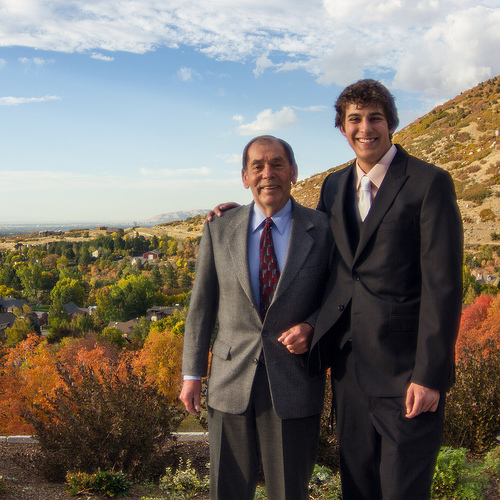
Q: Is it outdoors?
A: Yes, it is outdoors.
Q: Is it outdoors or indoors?
A: It is outdoors.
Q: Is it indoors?
A: No, it is outdoors.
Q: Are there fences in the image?
A: No, there are no fences.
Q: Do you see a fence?
A: No, there are no fences.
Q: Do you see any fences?
A: No, there are no fences.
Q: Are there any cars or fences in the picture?
A: No, there are no fences or cars.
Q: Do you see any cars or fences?
A: No, there are no fences or cars.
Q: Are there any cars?
A: No, there are no cars.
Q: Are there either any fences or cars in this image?
A: No, there are no cars or fences.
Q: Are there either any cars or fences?
A: No, there are no cars or fences.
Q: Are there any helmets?
A: No, there are no helmets.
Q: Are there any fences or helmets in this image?
A: No, there are no helmets or fences.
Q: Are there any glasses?
A: No, there are no glasses.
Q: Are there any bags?
A: No, there are no bags.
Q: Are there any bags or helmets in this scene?
A: No, there are no bags or helmets.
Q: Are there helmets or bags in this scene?
A: No, there are no bags or helmets.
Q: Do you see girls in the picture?
A: No, there are no girls.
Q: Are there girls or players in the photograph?
A: No, there are no girls or players.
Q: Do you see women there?
A: No, there are no women.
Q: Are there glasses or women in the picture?
A: No, there are no women or glasses.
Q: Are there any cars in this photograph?
A: No, there are no cars.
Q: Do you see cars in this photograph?
A: No, there are no cars.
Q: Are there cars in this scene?
A: No, there are no cars.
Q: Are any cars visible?
A: No, there are no cars.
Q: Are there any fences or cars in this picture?
A: No, there are no cars or fences.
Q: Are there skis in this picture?
A: No, there are no skis.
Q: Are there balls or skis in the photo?
A: No, there are no skis or balls.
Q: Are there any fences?
A: No, there are no fences.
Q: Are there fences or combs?
A: No, there are no fences or combs.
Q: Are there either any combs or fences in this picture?
A: No, there are no fences or combs.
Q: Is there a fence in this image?
A: No, there are no fences.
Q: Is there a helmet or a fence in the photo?
A: No, there are no fences or helmets.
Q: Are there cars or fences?
A: No, there are no cars or fences.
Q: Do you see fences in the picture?
A: No, there are no fences.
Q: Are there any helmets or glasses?
A: No, there are no glasses or helmets.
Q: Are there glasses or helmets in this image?
A: No, there are no glasses or helmets.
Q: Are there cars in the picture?
A: No, there are no cars.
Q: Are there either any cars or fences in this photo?
A: No, there are no cars or fences.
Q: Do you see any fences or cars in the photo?
A: No, there are no cars or fences.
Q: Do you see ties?
A: Yes, there is a tie.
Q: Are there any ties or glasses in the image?
A: Yes, there is a tie.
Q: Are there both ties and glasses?
A: No, there is a tie but no glasses.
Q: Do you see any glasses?
A: No, there are no glasses.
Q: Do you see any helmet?
A: No, there are no helmets.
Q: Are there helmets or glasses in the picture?
A: No, there are no helmets or glasses.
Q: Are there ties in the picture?
A: Yes, there is a tie.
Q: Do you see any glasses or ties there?
A: Yes, there is a tie.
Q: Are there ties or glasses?
A: Yes, there is a tie.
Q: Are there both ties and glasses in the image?
A: No, there is a tie but no glasses.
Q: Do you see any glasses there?
A: No, there are no glasses.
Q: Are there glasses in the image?
A: No, there are no glasses.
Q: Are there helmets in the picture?
A: No, there are no helmets.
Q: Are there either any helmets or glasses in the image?
A: No, there are no helmets or glasses.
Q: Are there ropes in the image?
A: No, there are no ropes.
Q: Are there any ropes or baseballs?
A: No, there are no ropes or baseballs.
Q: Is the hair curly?
A: Yes, the hair is curly.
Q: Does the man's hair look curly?
A: Yes, the hair is curly.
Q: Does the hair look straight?
A: No, the hair is curly.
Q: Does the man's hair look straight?
A: No, the hair is curly.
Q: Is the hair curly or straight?
A: The hair is curly.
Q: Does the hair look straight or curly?
A: The hair is curly.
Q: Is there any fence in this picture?
A: No, there are no fences.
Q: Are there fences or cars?
A: No, there are no fences or cars.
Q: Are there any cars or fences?
A: No, there are no fences or cars.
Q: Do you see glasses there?
A: No, there are no glasses.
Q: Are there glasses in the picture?
A: No, there are no glasses.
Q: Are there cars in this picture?
A: No, there are no cars.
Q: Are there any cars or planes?
A: No, there are no cars or planes.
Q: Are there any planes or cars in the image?
A: No, there are no cars or planes.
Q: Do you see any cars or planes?
A: No, there are no cars or planes.